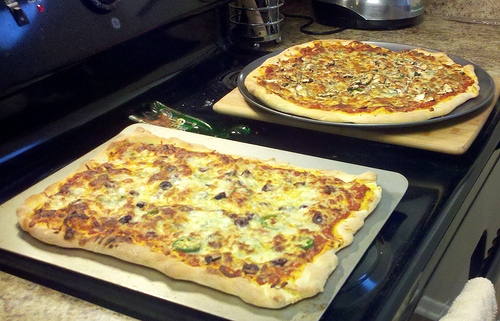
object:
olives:
[118, 214, 132, 224]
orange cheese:
[15, 127, 382, 309]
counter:
[435, 4, 500, 58]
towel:
[437, 276, 499, 320]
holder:
[228, 0, 285, 48]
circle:
[11, 1, 66, 17]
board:
[210, 77, 499, 156]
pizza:
[237, 38, 495, 126]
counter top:
[0, 275, 137, 320]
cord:
[284, 14, 346, 35]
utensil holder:
[225, 1, 286, 48]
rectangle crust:
[13, 125, 382, 311]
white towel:
[453, 282, 496, 318]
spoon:
[129, 100, 249, 140]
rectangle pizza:
[15, 129, 380, 311]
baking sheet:
[0, 120, 440, 321]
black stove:
[1, 1, 215, 113]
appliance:
[0, 2, 497, 310]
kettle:
[334, 0, 421, 31]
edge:
[212, 91, 231, 117]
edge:
[425, 138, 482, 154]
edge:
[488, 70, 500, 91]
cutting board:
[210, 75, 499, 155]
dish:
[0, 123, 409, 321]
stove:
[3, 5, 497, 316]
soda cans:
[242, 35, 482, 133]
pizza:
[243, 38, 481, 125]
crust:
[243, 38, 479, 123]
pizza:
[14, 123, 381, 311]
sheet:
[0, 123, 408, 321]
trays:
[0, 122, 409, 321]